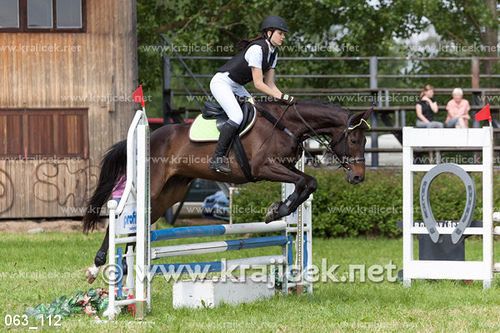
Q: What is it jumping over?
A: Sticks.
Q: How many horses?
A: 1.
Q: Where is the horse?
A: In the air.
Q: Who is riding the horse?
A: The girl.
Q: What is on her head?
A: Helmet.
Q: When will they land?
A: Soon.